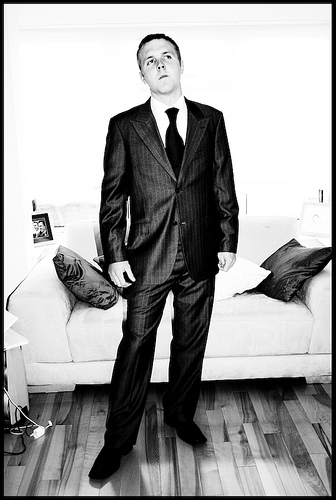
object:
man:
[86, 29, 241, 482]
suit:
[98, 94, 243, 451]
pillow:
[254, 237, 331, 303]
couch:
[2, 199, 331, 394]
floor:
[4, 376, 334, 498]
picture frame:
[32, 212, 54, 243]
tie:
[164, 106, 186, 181]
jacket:
[97, 94, 241, 284]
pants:
[103, 244, 219, 456]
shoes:
[87, 427, 133, 482]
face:
[137, 38, 180, 95]